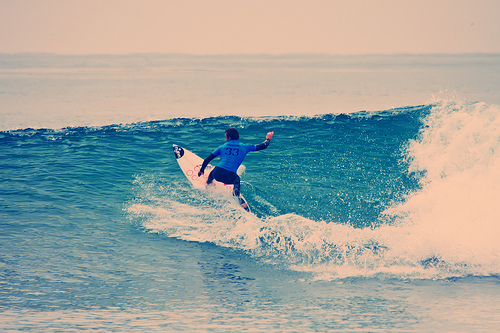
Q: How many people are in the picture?
A: One.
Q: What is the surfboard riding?
A: A wave.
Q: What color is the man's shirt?
A: Blue.